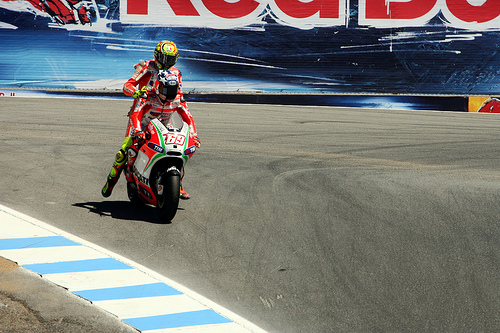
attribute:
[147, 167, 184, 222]
tire — smooth, black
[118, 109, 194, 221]
motorcycle — white, green, red, racing, colored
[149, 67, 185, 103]
helmet — colored, on, light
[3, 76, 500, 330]
race track — grey, blue, white, motorcycle, asphalt, colored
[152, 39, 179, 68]
helmet — yellow, colored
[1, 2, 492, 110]
track wall — blue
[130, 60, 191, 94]
suit — yellow, colored